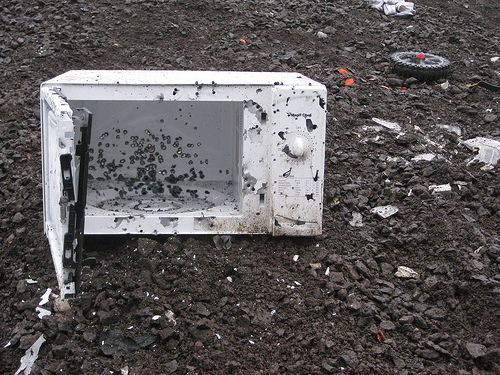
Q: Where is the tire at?
A: Behind microwave.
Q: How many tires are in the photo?
A: One.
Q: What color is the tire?
A: Black.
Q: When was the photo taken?
A: Daytime.